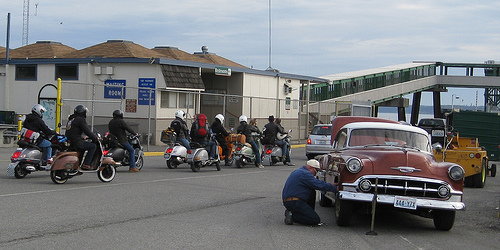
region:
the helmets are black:
[67, 103, 133, 120]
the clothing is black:
[71, 120, 132, 144]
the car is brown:
[323, 114, 473, 218]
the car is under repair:
[311, 107, 441, 217]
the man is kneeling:
[283, 139, 333, 225]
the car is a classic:
[309, 118, 464, 226]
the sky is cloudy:
[93, 6, 466, 46]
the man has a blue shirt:
[273, 156, 344, 201]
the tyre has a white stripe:
[96, 162, 130, 191]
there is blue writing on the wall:
[133, 77, 161, 107]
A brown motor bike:
[37, 125, 122, 190]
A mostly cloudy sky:
[150, 0, 440, 40]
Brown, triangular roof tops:
[1, 35, 251, 85]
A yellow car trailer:
[416, 120, 491, 190]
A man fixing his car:
[276, 106, 461, 236]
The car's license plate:
[388, 186, 423, 217]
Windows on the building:
[152, 86, 198, 108]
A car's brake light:
[313, 122, 333, 128]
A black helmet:
[111, 105, 121, 121]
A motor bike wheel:
[88, 157, 120, 183]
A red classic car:
[311, 107, 471, 235]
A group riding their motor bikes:
[3, 101, 300, 193]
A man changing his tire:
[277, 115, 372, 234]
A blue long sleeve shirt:
[281, 162, 337, 207]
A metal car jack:
[362, 173, 391, 240]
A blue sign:
[136, 74, 158, 108]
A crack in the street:
[12, 189, 281, 249]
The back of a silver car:
[298, 112, 355, 159]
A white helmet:
[211, 107, 228, 124]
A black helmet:
[71, 102, 93, 122]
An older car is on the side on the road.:
[322, 115, 464, 236]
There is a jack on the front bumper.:
[358, 172, 385, 247]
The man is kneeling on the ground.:
[273, 148, 339, 238]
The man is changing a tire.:
[281, 109, 470, 244]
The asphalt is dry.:
[4, 147, 499, 247]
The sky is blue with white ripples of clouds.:
[4, 2, 499, 72]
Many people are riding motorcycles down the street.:
[6, 100, 300, 192]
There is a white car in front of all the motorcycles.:
[303, 122, 343, 162]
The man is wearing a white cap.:
[298, 159, 330, 175]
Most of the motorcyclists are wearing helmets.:
[18, 96, 293, 142]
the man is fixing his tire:
[275, 148, 357, 240]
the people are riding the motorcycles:
[17, 82, 291, 169]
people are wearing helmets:
[24, 91, 134, 120]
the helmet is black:
[67, 90, 95, 123]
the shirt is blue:
[278, 158, 328, 204]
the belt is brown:
[275, 189, 312, 204]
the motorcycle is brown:
[47, 145, 148, 200]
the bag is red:
[190, 111, 212, 143]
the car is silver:
[293, 116, 336, 151]